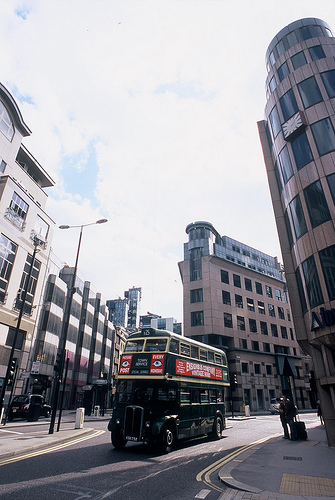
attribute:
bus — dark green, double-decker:
[100, 322, 253, 466]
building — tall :
[228, 13, 333, 300]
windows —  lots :
[284, 42, 329, 72]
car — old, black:
[5, 391, 51, 421]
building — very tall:
[255, 17, 333, 447]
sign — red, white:
[173, 355, 225, 380]